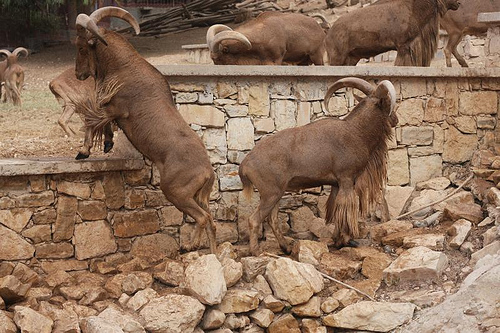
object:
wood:
[394, 175, 474, 219]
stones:
[103, 269, 155, 299]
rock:
[12, 305, 55, 332]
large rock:
[182, 253, 227, 305]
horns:
[86, 6, 141, 35]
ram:
[74, 6, 219, 257]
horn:
[210, 30, 253, 54]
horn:
[206, 24, 234, 53]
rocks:
[1, 273, 33, 302]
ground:
[0, 22, 235, 159]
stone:
[263, 255, 324, 305]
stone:
[81, 305, 146, 331]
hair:
[322, 121, 394, 227]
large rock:
[381, 245, 449, 288]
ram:
[206, 10, 327, 65]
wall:
[0, 11, 499, 280]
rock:
[321, 300, 417, 331]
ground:
[2, 185, 497, 332]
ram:
[237, 76, 399, 257]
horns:
[73, 13, 109, 47]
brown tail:
[236, 169, 253, 197]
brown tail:
[197, 175, 212, 206]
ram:
[0, 46, 29, 106]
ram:
[325, 0, 461, 66]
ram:
[50, 66, 100, 138]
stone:
[10, 219, 497, 328]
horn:
[373, 80, 397, 117]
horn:
[320, 75, 376, 117]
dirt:
[0, 24, 208, 159]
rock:
[137, 293, 205, 332]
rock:
[151, 257, 186, 286]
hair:
[332, 187, 360, 236]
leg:
[334, 175, 359, 249]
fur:
[64, 27, 216, 221]